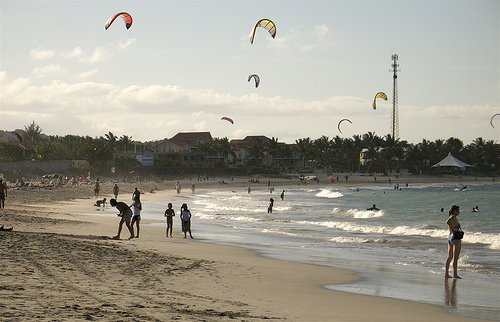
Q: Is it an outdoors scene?
A: Yes, it is outdoors.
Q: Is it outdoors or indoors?
A: It is outdoors.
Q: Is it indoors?
A: No, it is outdoors.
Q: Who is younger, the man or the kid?
A: The kid is younger than the man.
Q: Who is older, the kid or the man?
A: The man is older than the kid.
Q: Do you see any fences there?
A: No, there are no fences.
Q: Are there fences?
A: No, there are no fences.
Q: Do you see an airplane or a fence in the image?
A: No, there are no fences or airplanes.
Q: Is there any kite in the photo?
A: Yes, there is a kite.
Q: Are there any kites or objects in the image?
A: Yes, there is a kite.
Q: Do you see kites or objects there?
A: Yes, there is a kite.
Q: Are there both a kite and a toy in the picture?
A: No, there is a kite but no toys.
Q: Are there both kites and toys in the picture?
A: No, there is a kite but no toys.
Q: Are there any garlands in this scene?
A: No, there are no garlands.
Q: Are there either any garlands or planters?
A: No, there are no garlands or planters.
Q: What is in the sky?
A: The kite is in the sky.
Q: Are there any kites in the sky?
A: Yes, there is a kite in the sky.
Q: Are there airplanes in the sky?
A: No, there is a kite in the sky.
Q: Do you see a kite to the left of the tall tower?
A: Yes, there is a kite to the left of the tower.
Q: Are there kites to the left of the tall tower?
A: Yes, there is a kite to the left of the tower.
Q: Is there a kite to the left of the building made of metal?
A: Yes, there is a kite to the left of the tower.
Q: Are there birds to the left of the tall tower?
A: No, there is a kite to the left of the tower.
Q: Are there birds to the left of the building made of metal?
A: No, there is a kite to the left of the tower.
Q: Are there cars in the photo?
A: No, there are no cars.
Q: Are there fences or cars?
A: No, there are no cars or fences.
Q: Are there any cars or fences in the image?
A: No, there are no cars or fences.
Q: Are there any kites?
A: Yes, there is a kite.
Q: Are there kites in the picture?
A: Yes, there is a kite.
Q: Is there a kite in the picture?
A: Yes, there is a kite.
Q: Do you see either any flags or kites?
A: Yes, there is a kite.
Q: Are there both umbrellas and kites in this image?
A: No, there is a kite but no umbrellas.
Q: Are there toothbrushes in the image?
A: No, there are no toothbrushes.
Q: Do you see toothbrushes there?
A: No, there are no toothbrushes.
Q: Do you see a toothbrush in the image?
A: No, there are no toothbrushes.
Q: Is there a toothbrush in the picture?
A: No, there are no toothbrushes.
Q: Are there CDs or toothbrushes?
A: No, there are no toothbrushes or cds.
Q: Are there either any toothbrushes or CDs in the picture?
A: No, there are no toothbrushes or cds.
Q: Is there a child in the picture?
A: Yes, there is a child.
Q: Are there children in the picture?
A: Yes, there is a child.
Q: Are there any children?
A: Yes, there is a child.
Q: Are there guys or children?
A: Yes, there is a child.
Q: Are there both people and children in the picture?
A: Yes, there are both a child and a person.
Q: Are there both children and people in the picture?
A: Yes, there are both a child and a person.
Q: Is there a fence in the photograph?
A: No, there are no fences.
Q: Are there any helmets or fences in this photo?
A: No, there are no fences or helmets.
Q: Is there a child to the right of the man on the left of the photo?
A: Yes, there is a child to the right of the man.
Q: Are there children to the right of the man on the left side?
A: Yes, there is a child to the right of the man.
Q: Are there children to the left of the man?
A: No, the child is to the right of the man.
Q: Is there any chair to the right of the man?
A: No, there is a child to the right of the man.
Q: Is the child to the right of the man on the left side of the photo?
A: Yes, the child is to the right of the man.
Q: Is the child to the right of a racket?
A: No, the child is to the right of the man.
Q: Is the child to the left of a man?
A: No, the child is to the right of a man.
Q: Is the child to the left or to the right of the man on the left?
A: The child is to the right of the man.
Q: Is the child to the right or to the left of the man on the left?
A: The child is to the right of the man.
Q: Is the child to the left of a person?
A: No, the child is to the right of a person.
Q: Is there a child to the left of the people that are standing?
A: Yes, there is a child to the left of the people.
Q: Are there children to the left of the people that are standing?
A: Yes, there is a child to the left of the people.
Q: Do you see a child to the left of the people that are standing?
A: Yes, there is a child to the left of the people.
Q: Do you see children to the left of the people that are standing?
A: Yes, there is a child to the left of the people.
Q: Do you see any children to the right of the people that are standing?
A: No, the child is to the left of the people.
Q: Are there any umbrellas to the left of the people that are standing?
A: No, there is a child to the left of the people.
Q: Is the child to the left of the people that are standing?
A: Yes, the child is to the left of the people.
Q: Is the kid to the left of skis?
A: No, the kid is to the left of the people.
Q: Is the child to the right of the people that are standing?
A: No, the child is to the left of the people.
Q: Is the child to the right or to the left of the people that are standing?
A: The child is to the left of the people.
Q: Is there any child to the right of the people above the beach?
A: Yes, there is a child to the right of the people.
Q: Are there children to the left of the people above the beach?
A: No, the child is to the right of the people.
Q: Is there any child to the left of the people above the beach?
A: No, the child is to the right of the people.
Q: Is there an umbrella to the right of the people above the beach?
A: No, there is a child to the right of the people.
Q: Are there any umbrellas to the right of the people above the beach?
A: No, there is a child to the right of the people.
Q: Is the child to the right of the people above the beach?
A: Yes, the child is to the right of the people.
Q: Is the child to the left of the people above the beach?
A: No, the child is to the right of the people.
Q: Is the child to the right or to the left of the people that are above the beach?
A: The child is to the right of the people.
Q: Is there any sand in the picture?
A: Yes, there is sand.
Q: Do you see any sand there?
A: Yes, there is sand.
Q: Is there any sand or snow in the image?
A: Yes, there is sand.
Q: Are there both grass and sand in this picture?
A: No, there is sand but no grass.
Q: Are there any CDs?
A: No, there are no cds.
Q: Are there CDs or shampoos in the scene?
A: No, there are no CDs or shampoos.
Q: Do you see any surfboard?
A: No, there are no surfboards.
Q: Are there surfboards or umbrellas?
A: No, there are no surfboards or umbrellas.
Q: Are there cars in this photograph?
A: No, there are no cars.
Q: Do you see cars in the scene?
A: No, there are no cars.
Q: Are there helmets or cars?
A: No, there are no cars or helmets.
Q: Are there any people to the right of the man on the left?
A: Yes, there is a person to the right of the man.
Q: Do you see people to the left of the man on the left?
A: No, the person is to the right of the man.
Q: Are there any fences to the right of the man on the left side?
A: No, there is a person to the right of the man.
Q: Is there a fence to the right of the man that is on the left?
A: No, there is a person to the right of the man.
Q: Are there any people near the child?
A: Yes, there is a person near the child.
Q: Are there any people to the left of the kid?
A: Yes, there is a person to the left of the kid.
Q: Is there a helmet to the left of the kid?
A: No, there is a person to the left of the kid.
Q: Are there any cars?
A: No, there are no cars.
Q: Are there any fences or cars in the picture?
A: No, there are no cars or fences.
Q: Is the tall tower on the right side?
A: Yes, the tower is on the right of the image.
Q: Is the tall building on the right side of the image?
A: Yes, the tower is on the right of the image.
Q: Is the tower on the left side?
A: No, the tower is on the right of the image.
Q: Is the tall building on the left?
A: No, the tower is on the right of the image.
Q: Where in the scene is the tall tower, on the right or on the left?
A: The tower is on the right of the image.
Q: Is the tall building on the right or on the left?
A: The tower is on the right of the image.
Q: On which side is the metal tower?
A: The tower is on the right of the image.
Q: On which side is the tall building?
A: The tower is on the right of the image.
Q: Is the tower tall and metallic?
A: Yes, the tower is tall and metallic.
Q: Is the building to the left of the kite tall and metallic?
A: Yes, the tower is tall and metallic.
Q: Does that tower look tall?
A: Yes, the tower is tall.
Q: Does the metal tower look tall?
A: Yes, the tower is tall.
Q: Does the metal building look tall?
A: Yes, the tower is tall.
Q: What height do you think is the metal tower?
A: The tower is tall.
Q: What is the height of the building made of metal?
A: The tower is tall.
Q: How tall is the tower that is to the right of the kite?
A: The tower is tall.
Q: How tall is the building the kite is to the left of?
A: The tower is tall.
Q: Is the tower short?
A: No, the tower is tall.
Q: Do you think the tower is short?
A: No, the tower is tall.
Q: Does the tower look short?
A: No, the tower is tall.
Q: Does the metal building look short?
A: No, the tower is tall.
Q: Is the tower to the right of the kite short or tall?
A: The tower is tall.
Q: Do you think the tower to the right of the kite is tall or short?
A: The tower is tall.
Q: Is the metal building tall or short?
A: The tower is tall.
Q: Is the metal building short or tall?
A: The tower is tall.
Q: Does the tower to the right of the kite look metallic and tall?
A: Yes, the tower is metallic and tall.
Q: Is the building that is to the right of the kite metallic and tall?
A: Yes, the tower is metallic and tall.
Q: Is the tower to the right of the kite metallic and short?
A: No, the tower is metallic but tall.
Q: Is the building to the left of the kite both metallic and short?
A: No, the tower is metallic but tall.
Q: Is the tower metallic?
A: Yes, the tower is metallic.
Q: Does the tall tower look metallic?
A: Yes, the tower is metallic.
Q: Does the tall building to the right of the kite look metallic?
A: Yes, the tower is metallic.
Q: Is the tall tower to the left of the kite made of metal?
A: Yes, the tower is made of metal.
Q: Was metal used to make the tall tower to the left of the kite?
A: Yes, the tower is made of metal.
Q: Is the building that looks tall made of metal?
A: Yes, the tower is made of metal.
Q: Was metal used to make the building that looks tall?
A: Yes, the tower is made of metal.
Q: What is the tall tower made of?
A: The tower is made of metal.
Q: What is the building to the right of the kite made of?
A: The tower is made of metal.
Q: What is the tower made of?
A: The tower is made of metal.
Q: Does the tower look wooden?
A: No, the tower is metallic.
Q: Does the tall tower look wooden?
A: No, the tower is metallic.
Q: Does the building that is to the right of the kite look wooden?
A: No, the tower is metallic.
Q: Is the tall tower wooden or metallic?
A: The tower is metallic.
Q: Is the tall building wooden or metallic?
A: The tower is metallic.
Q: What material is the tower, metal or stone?
A: The tower is made of metal.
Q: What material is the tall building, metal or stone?
A: The tower is made of metal.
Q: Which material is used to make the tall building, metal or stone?
A: The tower is made of metal.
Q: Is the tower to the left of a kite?
A: Yes, the tower is to the left of a kite.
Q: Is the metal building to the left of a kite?
A: Yes, the tower is to the left of a kite.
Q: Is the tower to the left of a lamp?
A: No, the tower is to the left of a kite.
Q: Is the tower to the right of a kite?
A: Yes, the tower is to the right of a kite.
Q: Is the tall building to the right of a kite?
A: Yes, the tower is to the right of a kite.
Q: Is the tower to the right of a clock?
A: No, the tower is to the right of a kite.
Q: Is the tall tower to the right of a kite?
A: Yes, the tower is to the right of a kite.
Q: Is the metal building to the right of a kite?
A: Yes, the tower is to the right of a kite.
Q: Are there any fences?
A: No, there are no fences.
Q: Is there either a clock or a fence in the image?
A: No, there are no fences or clocks.